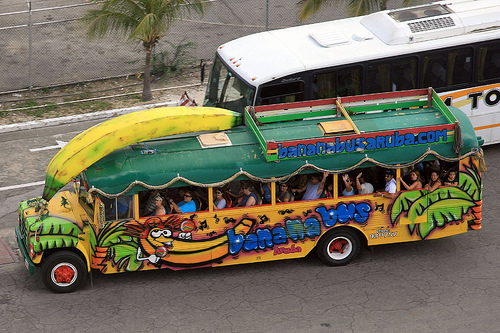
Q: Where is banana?
A: On bus.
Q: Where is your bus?
A: Aruba.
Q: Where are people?
A: On bus.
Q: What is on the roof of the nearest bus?
A: A giant banana.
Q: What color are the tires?
A: Black.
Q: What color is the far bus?
A: White.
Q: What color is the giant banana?
A: Yellow and green.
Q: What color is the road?
A: Gray.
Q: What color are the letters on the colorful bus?
A: Blue.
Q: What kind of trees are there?
A: Palm trees.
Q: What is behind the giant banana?
A: A cargo hold.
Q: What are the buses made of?
A: Metal.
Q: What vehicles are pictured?
A: Busses.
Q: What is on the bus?
A: A group of people.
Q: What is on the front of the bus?
A: A large banana.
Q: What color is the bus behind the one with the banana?
A: White.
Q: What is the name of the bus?
A: Banana Bus.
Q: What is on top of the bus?
A: A banana.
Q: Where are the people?
A: On the bus.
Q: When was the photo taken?
A: Daytime.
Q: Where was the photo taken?
A: Aruba.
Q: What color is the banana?
A: Yellow and green.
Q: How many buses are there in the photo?
A: Two.